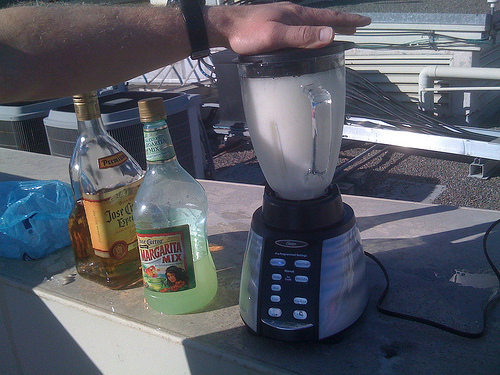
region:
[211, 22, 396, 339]
this is a blender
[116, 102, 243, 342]
this is a botttle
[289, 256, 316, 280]
a button on the blender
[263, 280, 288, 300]
a button on the blender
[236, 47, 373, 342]
a blender with a mixture in it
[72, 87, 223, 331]
a couple bottles of alcohol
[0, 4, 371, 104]
an arm reaches out to close a blender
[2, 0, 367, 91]
an arm with a wristwatch on it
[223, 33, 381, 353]
a blender with an alcoholic beverage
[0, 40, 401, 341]
a setup to make adult beverages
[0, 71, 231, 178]
a couple of air conditioner units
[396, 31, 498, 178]
pipes and gutter systems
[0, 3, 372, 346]
hand on top of blender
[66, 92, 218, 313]
two bottles with labels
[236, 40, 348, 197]
white liquid in blender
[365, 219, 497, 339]
black wire of blender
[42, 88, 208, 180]
central air conditioning unit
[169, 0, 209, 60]
black band of watch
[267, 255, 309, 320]
buttons on front of blender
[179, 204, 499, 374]
shadows on gray surface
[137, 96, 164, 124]
gold cap of bottle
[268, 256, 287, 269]
white button on blender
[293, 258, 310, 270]
white button on blender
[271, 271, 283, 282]
white button on blender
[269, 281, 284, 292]
white button on blender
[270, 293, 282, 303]
white button on blender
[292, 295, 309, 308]
white button on blender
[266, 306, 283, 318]
white button on blender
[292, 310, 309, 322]
white button on blender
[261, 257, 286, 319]
white buttons on blender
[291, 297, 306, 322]
white buttons on blender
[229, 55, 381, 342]
A blender with a drink.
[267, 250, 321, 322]
The buttons on a blender.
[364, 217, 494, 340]
The cord for the blender.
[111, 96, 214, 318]
The bottle of margarita mix.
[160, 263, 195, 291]
The woman on the bottle of margarita mix.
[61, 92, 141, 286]
The bottle next to the margarita mix.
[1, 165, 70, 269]
The blue bag on the table.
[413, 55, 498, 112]
The white pipe in the background.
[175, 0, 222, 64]
The watch on the man's hand.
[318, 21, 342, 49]
A man's fingernail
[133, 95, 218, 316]
bottle of drink mix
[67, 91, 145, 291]
big bottle of tequilla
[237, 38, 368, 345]
blender mixing a drink